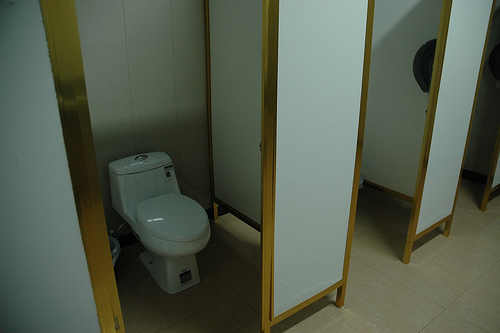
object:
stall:
[74, 1, 264, 331]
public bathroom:
[0, 0, 499, 332]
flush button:
[134, 155, 148, 162]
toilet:
[109, 149, 212, 294]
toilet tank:
[108, 150, 181, 215]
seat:
[134, 192, 211, 243]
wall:
[207, 0, 262, 230]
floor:
[114, 180, 498, 332]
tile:
[350, 208, 500, 311]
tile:
[125, 41, 176, 108]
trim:
[41, 1, 126, 331]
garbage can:
[108, 235, 122, 268]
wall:
[76, 0, 212, 248]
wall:
[261, 2, 376, 331]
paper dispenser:
[412, 38, 437, 93]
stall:
[332, 1, 496, 308]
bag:
[107, 235, 121, 268]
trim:
[259, 1, 282, 332]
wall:
[364, 1, 442, 201]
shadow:
[116, 223, 337, 332]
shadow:
[358, 186, 446, 259]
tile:
[75, 1, 128, 46]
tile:
[123, 1, 173, 31]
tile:
[83, 44, 129, 99]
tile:
[174, 97, 209, 145]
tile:
[173, 44, 207, 94]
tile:
[171, 1, 213, 53]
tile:
[92, 103, 134, 149]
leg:
[336, 286, 346, 307]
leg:
[264, 325, 272, 332]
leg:
[401, 236, 414, 264]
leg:
[444, 217, 452, 237]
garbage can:
[358, 176, 364, 188]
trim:
[335, 0, 375, 309]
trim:
[403, 0, 453, 265]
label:
[164, 164, 175, 179]